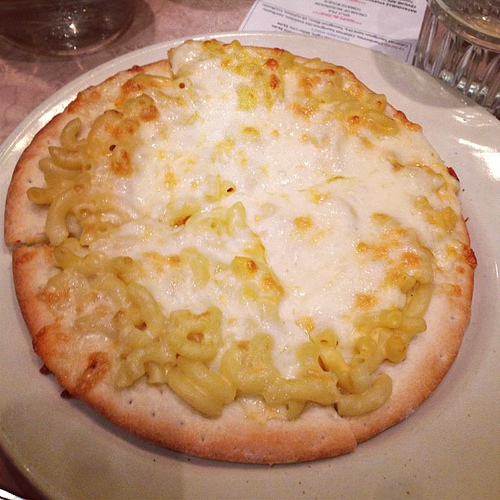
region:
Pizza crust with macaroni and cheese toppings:
[6, 38, 476, 471]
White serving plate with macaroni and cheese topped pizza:
[2, 30, 499, 499]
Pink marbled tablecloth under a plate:
[3, 0, 256, 157]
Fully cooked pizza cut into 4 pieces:
[0, 40, 472, 472]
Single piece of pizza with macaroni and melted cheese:
[4, 201, 367, 468]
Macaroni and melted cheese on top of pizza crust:
[3, 34, 478, 467]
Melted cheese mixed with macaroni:
[136, 115, 393, 352]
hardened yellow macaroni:
[171, 363, 233, 419]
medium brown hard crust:
[195, 425, 357, 465]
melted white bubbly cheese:
[289, 245, 346, 302]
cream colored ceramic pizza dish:
[401, 431, 497, 498]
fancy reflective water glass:
[426, 4, 498, 88]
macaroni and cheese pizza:
[18, 48, 472, 462]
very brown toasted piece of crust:
[67, 350, 109, 400]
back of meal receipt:
[253, 0, 427, 62]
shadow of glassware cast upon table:
[11, 16, 151, 82]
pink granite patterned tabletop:
[0, 56, 65, 140]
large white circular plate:
[1, 32, 498, 499]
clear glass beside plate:
[416, 1, 499, 122]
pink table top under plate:
[1, 0, 499, 498]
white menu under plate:
[236, 0, 428, 66]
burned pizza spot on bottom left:
[33, 325, 107, 407]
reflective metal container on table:
[0, 3, 137, 58]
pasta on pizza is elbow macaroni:
[28, 39, 431, 420]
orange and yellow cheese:
[32, 39, 464, 414]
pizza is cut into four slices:
[4, 40, 472, 465]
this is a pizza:
[11, 56, 499, 483]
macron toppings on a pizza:
[166, 307, 246, 433]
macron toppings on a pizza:
[106, 273, 183, 400]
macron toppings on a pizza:
[346, 291, 418, 360]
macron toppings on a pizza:
[36, 126, 88, 208]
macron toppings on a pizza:
[83, 106, 149, 168]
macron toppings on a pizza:
[281, 52, 362, 129]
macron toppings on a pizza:
[131, 314, 230, 440]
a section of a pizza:
[260, 295, 410, 471]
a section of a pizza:
[145, 278, 320, 498]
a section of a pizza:
[27, 212, 281, 484]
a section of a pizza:
[288, 193, 471, 427]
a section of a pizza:
[5, 119, 208, 394]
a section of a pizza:
[97, 69, 330, 231]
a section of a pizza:
[165, 35, 425, 229]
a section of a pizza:
[265, 152, 495, 414]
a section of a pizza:
[11, 242, 298, 472]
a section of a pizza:
[9, 85, 262, 267]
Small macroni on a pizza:
[108, 339, 161, 393]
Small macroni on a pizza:
[175, 346, 229, 412]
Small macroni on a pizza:
[210, 346, 260, 395]